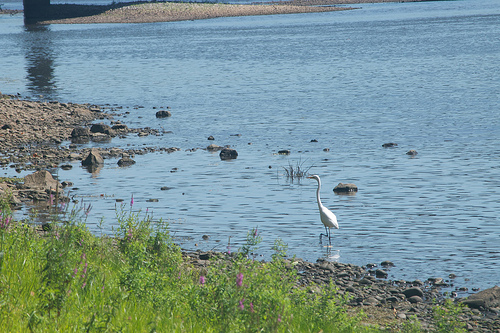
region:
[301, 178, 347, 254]
white bird standing in water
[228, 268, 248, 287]
purple flower in green grass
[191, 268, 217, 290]
purple flower in green grass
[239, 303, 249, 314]
purple flower in green grass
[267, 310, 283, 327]
purple flower in green grass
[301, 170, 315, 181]
beak of white bird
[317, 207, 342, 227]
body of white bird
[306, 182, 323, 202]
neck of white bird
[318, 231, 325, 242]
leg of white bird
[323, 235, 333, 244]
leg of white bird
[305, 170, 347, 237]
the bird is white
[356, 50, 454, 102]
the water is still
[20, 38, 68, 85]
the reflection is on the water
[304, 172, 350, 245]
the bird is in the water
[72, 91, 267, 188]
the rocks are in the water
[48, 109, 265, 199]
the rocks are brown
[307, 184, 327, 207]
the bird has a neck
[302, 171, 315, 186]
the bird has a beak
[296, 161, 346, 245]
the bird is standing on one foot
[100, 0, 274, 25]
the ground is brown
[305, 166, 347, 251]
A crane in the water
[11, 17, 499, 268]
A large body of water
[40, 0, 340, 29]
A rocky shore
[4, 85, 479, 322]
A rocky shore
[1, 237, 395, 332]
some grass above the shore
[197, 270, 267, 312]
some pink flowers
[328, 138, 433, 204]
some rocks in the water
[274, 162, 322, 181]
some grass in the water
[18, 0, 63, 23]
A stone support beam for a bridge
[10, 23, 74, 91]
reflection of the support beam in the water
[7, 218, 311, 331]
a green patch of grass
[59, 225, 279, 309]
some purple flowers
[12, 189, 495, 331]
a shoreline of rocks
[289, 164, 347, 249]
a white bird in water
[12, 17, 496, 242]
a blue river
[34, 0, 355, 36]
rocks in the background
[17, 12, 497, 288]
scene happening outside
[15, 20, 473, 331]
scene during the day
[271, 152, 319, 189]
grass blades coming out of the water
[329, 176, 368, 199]
a gray rock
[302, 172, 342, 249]
bird in the water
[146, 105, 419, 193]
small rocks on the waters surface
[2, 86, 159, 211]
rocky beach area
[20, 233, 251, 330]
tall grass and weeds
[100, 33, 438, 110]
ripples in blue water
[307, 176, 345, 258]
bird with one leg out of the water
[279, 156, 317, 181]
weeds sticking out of the water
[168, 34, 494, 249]
clean blue water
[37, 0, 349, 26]
rocky piece of land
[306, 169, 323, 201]
tall thin bird neck